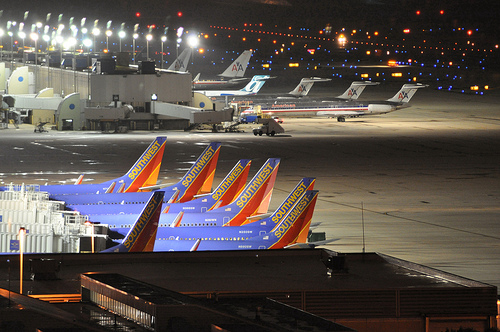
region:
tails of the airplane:
[268, 170, 320, 238]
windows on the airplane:
[183, 218, 213, 228]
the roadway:
[362, 195, 477, 241]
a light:
[183, 33, 208, 47]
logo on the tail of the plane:
[347, 86, 359, 97]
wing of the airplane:
[320, 106, 360, 119]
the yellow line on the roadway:
[387, 203, 418, 218]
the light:
[336, 31, 350, 48]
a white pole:
[15, 228, 33, 298]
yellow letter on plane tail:
[273, 227, 282, 239]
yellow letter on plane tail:
[278, 224, 288, 234]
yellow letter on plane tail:
[280, 220, 289, 228]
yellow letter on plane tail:
[282, 215, 292, 225]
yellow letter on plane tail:
[286, 211, 295, 220]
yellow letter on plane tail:
[290, 206, 301, 216]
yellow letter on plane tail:
[296, 198, 306, 213]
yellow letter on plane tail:
[298, 195, 308, 208]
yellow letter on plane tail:
[301, 194, 312, 202]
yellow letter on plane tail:
[268, 213, 279, 223]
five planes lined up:
[62, 146, 312, 241]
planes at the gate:
[197, 68, 444, 130]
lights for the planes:
[18, 23, 209, 51]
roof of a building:
[61, 249, 487, 312]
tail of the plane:
[392, 74, 410, 113]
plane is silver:
[261, 98, 395, 117]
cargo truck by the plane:
[251, 111, 286, 141]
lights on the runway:
[413, 51, 486, 102]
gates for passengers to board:
[4, 189, 88, 256]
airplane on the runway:
[133, 208, 328, 247]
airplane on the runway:
[130, 181, 280, 221]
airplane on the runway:
[72, 147, 174, 184]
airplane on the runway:
[118, 188, 162, 254]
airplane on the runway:
[137, 157, 224, 192]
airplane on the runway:
[254, 83, 421, 118]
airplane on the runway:
[249, 78, 379, 101]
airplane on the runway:
[186, 70, 284, 89]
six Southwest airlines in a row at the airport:
[48, 136, 335, 247]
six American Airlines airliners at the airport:
[159, 35, 423, 123]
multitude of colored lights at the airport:
[250, 16, 482, 81]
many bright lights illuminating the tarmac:
[5, 6, 200, 53]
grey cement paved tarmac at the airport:
[318, 140, 496, 227]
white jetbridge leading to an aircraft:
[148, 101, 233, 127]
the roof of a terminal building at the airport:
[165, 251, 476, 316]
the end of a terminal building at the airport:
[77, 70, 200, 108]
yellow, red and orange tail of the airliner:
[123, 134, 175, 183]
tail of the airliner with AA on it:
[214, 49, 258, 76]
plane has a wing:
[312, 109, 377, 119]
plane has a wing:
[116, 187, 163, 252]